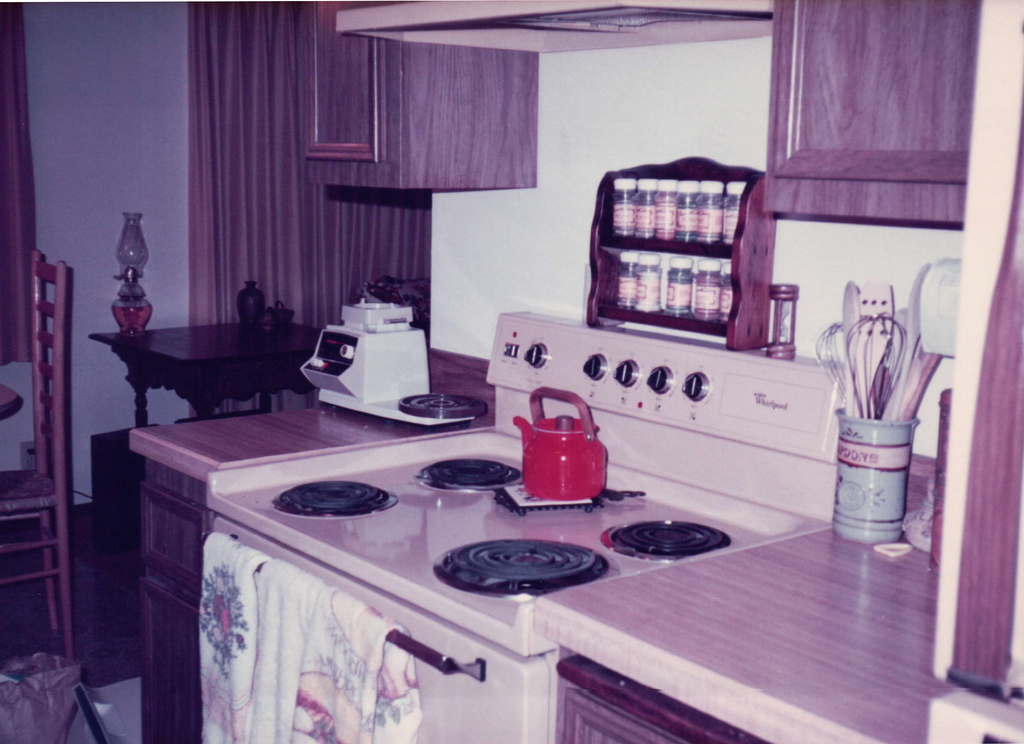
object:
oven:
[202, 244, 827, 744]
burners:
[271, 456, 736, 598]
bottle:
[655, 180, 677, 241]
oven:
[206, 510, 567, 744]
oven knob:
[646, 366, 673, 393]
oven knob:
[682, 371, 710, 402]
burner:
[414, 458, 523, 493]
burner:
[600, 520, 731, 559]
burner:
[432, 539, 612, 599]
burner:
[274, 480, 400, 518]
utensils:
[814, 280, 946, 416]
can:
[832, 407, 920, 543]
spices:
[610, 177, 752, 325]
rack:
[586, 155, 777, 351]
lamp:
[110, 212, 153, 334]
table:
[88, 320, 342, 429]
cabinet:
[298, 25, 541, 201]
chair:
[0, 247, 79, 671]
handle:
[381, 630, 490, 686]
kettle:
[512, 386, 610, 500]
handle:
[529, 386, 597, 441]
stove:
[203, 441, 795, 662]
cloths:
[197, 533, 425, 744]